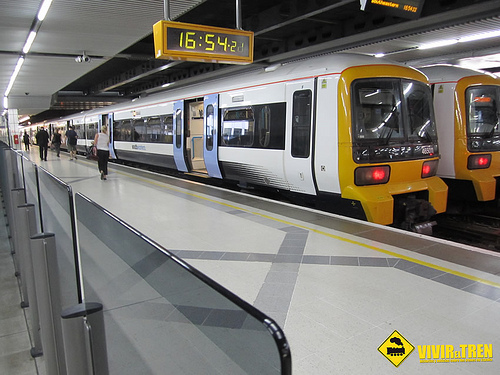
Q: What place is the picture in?
A: It is at the train station.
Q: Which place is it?
A: It is a train station.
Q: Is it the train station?
A: Yes, it is the train station.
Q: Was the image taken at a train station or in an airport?
A: It was taken at a train station.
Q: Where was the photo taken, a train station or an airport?
A: It was taken at a train station.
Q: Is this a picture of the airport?
A: No, the picture is showing the train station.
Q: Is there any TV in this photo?
A: No, there are no televisions.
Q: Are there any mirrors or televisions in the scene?
A: No, there are no televisions or mirrors.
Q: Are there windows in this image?
A: Yes, there is a window.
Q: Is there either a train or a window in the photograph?
A: Yes, there is a window.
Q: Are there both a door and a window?
A: Yes, there are both a window and a door.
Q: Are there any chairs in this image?
A: No, there are no chairs.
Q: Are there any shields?
A: No, there are no shields.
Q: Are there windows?
A: Yes, there is a window.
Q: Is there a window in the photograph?
A: Yes, there is a window.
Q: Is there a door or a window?
A: Yes, there is a window.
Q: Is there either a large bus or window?
A: Yes, there is a large window.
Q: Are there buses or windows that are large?
A: Yes, the window is large.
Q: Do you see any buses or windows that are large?
A: Yes, the window is large.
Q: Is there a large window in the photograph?
A: Yes, there is a large window.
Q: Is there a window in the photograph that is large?
A: Yes, there is a window that is large.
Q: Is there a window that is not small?
A: Yes, there is a large window.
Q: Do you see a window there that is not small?
A: Yes, there is a large window.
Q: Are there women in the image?
A: Yes, there is a woman.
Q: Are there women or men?
A: Yes, there is a woman.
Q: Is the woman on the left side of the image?
A: Yes, the woman is on the left of the image.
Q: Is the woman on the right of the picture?
A: No, the woman is on the left of the image.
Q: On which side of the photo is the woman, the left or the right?
A: The woman is on the left of the image.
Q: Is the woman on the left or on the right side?
A: The woman is on the left of the image.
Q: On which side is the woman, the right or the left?
A: The woman is on the left of the image.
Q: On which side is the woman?
A: The woman is on the left of the image.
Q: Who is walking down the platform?
A: The woman is walking down the platform.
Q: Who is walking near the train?
A: The woman is walking near the train.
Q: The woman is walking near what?
A: The woman is walking by the train.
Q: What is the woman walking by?
A: The woman is walking by the train.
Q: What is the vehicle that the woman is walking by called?
A: The vehicle is a train.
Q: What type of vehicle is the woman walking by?
A: The woman is walking by the train.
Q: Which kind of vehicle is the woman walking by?
A: The woman is walking by the train.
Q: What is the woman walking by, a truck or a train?
A: The woman is walking by a train.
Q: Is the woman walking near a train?
A: Yes, the woman is walking near a train.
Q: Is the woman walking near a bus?
A: No, the woman is walking near a train.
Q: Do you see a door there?
A: Yes, there is a door.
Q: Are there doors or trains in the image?
A: Yes, there is a door.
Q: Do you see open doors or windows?
A: Yes, there is an open door.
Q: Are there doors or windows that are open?
A: Yes, the door is open.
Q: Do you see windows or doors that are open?
A: Yes, the door is open.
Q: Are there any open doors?
A: Yes, there is an open door.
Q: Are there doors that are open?
A: Yes, there is a door that is open.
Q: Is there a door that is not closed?
A: Yes, there is a open door.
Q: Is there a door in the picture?
A: Yes, there is a door.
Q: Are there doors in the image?
A: Yes, there is a door.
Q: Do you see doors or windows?
A: Yes, there is a door.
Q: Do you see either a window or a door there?
A: Yes, there is a door.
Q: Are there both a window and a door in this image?
A: Yes, there are both a door and a window.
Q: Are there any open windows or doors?
A: Yes, there is an open door.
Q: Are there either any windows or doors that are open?
A: Yes, the door is open.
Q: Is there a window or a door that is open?
A: Yes, the door is open.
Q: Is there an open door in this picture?
A: Yes, there is an open door.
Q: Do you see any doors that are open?
A: Yes, there is a door that is open.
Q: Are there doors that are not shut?
A: Yes, there is a open door.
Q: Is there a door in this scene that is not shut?
A: Yes, there is a open door.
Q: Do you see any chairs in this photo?
A: No, there are no chairs.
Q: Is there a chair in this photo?
A: No, there are no chairs.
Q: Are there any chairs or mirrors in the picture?
A: No, there are no chairs or mirrors.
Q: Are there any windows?
A: Yes, there is a window.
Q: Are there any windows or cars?
A: Yes, there is a window.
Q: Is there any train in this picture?
A: Yes, there is a train.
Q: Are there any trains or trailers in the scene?
A: Yes, there is a train.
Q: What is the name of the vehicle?
A: The vehicle is a train.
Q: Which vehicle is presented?
A: The vehicle is a train.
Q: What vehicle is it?
A: The vehicle is a train.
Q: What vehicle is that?
A: This is a train.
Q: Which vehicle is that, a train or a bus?
A: This is a train.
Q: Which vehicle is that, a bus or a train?
A: This is a train.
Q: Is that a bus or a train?
A: That is a train.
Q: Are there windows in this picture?
A: Yes, there is a window.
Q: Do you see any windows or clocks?
A: Yes, there is a window.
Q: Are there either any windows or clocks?
A: Yes, there is a window.